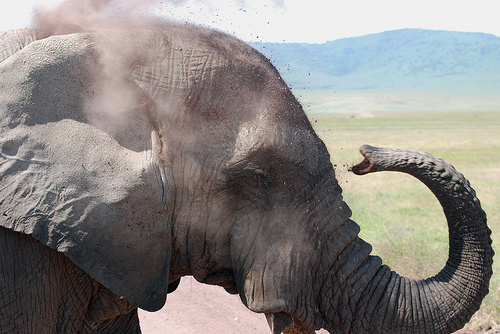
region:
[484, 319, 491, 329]
black mark is spotted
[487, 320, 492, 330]
black mark is spotted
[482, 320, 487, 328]
black mark is spotted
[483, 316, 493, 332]
black mark is spotted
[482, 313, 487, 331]
black mark is spotted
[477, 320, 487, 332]
black mark is spotted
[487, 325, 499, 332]
black mark is spotted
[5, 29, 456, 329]
a very old elephant in the wild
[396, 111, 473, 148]
green grass in the field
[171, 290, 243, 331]
dirt road for the vehicles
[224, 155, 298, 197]
the eye of the elephant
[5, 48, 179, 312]
the elephants ear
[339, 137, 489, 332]
the trunk of the elephant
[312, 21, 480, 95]
mountains in the background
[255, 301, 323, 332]
the mouth of the elephant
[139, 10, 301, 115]
the forehead of the elephant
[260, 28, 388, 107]
thrown dirt from the elephant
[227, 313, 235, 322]
white mark is spotted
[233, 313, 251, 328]
white mark is spotted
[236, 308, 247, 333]
white mark is spotted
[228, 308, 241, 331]
white mark is spotted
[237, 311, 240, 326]
white mark is spotted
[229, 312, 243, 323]
white mark is spotted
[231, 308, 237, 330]
white mark is spotted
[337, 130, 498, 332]
curled elephant trunk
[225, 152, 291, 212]
left eye of the elephant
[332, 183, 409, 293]
ridges along the trunk of the elephant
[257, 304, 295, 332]
stub of the elephant's tusk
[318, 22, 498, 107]
mountain in the distance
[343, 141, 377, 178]
opening at the end of the trunk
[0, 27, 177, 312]
ear of the elephant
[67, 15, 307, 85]
top of the elephant's head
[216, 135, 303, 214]
an open elephant's eye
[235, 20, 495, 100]
hilly area in the background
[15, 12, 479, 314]
Elephant with lifted trunk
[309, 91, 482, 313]
Elephant throwing dirt on itself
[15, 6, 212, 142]
Dust from the dirt that the elephant threw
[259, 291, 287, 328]
Elephant tusks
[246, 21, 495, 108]
Mountains in the background with trees and foilage on them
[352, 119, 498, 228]
grass in sahara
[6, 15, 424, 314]
Elephant in natural habitat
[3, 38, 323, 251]
African elephant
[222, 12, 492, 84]
orange cloudless sky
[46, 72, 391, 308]
grey elephant